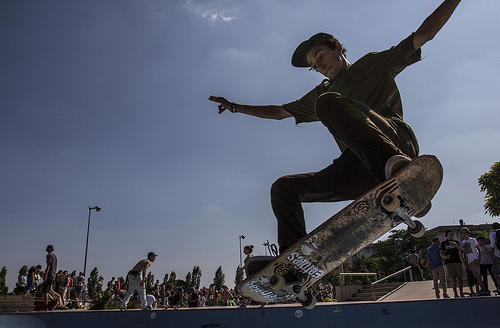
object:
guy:
[208, 2, 472, 273]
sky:
[1, 5, 497, 285]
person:
[425, 236, 449, 299]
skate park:
[2, 259, 498, 327]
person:
[442, 228, 468, 299]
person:
[459, 226, 490, 297]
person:
[41, 244, 60, 313]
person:
[121, 250, 157, 311]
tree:
[479, 159, 498, 215]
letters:
[287, 252, 325, 281]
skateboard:
[237, 152, 443, 312]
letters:
[248, 280, 282, 303]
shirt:
[131, 258, 151, 275]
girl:
[241, 244, 258, 270]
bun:
[249, 245, 253, 249]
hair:
[243, 245, 255, 254]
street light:
[83, 205, 103, 286]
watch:
[231, 101, 236, 114]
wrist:
[228, 102, 240, 115]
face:
[306, 44, 345, 81]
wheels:
[381, 193, 425, 239]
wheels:
[271, 275, 318, 311]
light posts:
[238, 233, 246, 274]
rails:
[370, 264, 414, 306]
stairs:
[348, 279, 405, 303]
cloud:
[191, 4, 242, 26]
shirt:
[282, 32, 423, 152]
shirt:
[459, 237, 481, 264]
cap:
[291, 33, 334, 69]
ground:
[2, 301, 499, 326]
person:
[182, 286, 200, 308]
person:
[406, 250, 425, 282]